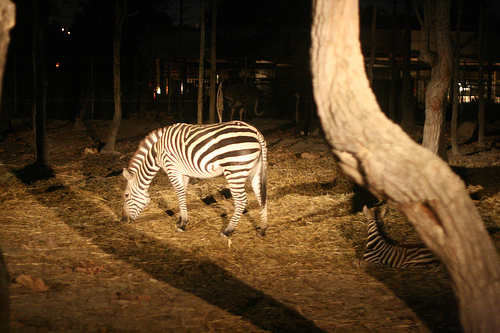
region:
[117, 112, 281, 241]
STRIPED ZEBRA GRAZING IN PADDOCK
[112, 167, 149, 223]
HEAD OF STRIPED ZEBRA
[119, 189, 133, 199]
EAR OF STRIPED ZEBRA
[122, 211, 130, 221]
NOSE OF STRIPED ZEBRA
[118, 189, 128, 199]
EYE OF STRIPED ZEBRA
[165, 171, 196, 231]
LEG OF STRIPED ZEBRA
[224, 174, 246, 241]
LEG OF STRIPED ZEBRA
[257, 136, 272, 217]
TAIL OF STRIPED ZEBRA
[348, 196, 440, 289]
SMALL ZEBRA LYING DOWN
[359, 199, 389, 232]
HEAD OF SMALL ZEBRA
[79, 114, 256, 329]
the zebra is grazing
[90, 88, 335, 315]
the zebra is striped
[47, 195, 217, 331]
hay is on the ground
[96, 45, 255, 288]
a flash is on the zebra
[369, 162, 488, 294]
a hole is on the tree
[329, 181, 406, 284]
the zebra is sitting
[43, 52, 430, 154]
tall trees are in the background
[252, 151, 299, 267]
the tail is black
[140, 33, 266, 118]
a car is parked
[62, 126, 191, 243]
dirt is below the tree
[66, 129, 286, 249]
a zebra that is eating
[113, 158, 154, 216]
the head of a zebra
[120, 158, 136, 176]
the ear of a zebra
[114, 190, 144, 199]
the eye of a zebra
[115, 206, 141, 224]
the nose of a zebra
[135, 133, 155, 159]
the mane of a zebra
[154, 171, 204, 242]
the front legs of a zebra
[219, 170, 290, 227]
the back legs of a zebra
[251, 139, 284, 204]
the tail of a zebra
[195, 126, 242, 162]
the stripes of a zebra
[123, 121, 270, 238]
stripes on the grazing, standing zebra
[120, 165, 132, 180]
grazing, standing zebra's ear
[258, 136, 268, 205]
grazing, standing zebra's tail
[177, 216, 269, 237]
grazing, standing zebra's hooves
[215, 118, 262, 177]
grazing, standing zebra's rump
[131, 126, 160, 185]
grazing, standing zebra's neck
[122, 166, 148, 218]
grazing, standing zebra's head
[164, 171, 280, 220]
grazing, standing zebra's legs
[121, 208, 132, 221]
grazing, standing zebra's nose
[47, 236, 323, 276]
The hay on the ground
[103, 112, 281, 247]
The zebra is eating hay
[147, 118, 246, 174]
The zebra is the color black and white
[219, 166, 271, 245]
The back legs of the zebra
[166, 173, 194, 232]
The front legs of the zebra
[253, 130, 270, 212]
The tail of the zebra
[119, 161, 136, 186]
The ear of the zebra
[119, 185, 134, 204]
The eye of the zebra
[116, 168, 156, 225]
The head of the zebra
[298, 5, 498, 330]
The tree trunk is the color brown